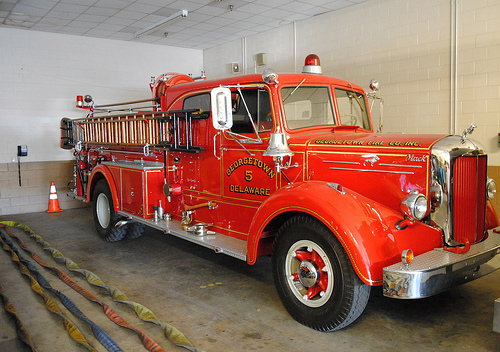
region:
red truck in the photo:
[51, 35, 485, 292]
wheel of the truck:
[283, 193, 395, 305]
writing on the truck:
[208, 141, 284, 212]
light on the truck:
[390, 183, 434, 245]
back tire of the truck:
[83, 173, 131, 248]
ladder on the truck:
[63, 100, 213, 175]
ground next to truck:
[144, 260, 206, 318]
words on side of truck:
[209, 149, 283, 210]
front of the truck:
[410, 122, 494, 276]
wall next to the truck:
[391, 28, 441, 84]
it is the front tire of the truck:
[268, 221, 355, 328]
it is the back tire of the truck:
[92, 177, 124, 242]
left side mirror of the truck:
[208, 87, 243, 132]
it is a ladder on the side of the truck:
[63, 110, 198, 151]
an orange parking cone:
[43, 176, 68, 216]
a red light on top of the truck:
[299, 53, 328, 72]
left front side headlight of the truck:
[405, 190, 430, 220]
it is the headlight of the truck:
[485, 180, 499, 199]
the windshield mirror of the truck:
[273, 85, 373, 135]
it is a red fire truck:
[66, 64, 488, 326]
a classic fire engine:
[59, 50, 499, 332]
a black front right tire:
[270, 211, 373, 330]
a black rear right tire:
[89, 176, 126, 242]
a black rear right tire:
[124, 218, 143, 237]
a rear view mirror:
[211, 85, 232, 129]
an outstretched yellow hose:
[12, 217, 200, 350]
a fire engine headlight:
[402, 192, 427, 219]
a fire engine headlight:
[484, 176, 499, 200]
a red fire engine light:
[302, 51, 326, 73]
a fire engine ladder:
[69, 106, 211, 155]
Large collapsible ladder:
[66, 107, 207, 148]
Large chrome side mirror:
[210, 77, 262, 137]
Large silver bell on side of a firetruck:
[262, 125, 297, 166]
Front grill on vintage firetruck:
[435, 135, 490, 240]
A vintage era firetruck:
[65, 52, 495, 323]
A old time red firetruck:
[67, 52, 497, 327]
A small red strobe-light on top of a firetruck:
[300, 52, 320, 67]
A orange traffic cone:
[47, 180, 61, 210]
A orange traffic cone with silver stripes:
[44, 182, 64, 209]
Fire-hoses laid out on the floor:
[0, 216, 201, 348]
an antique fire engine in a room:
[60, 53, 497, 331]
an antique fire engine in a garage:
[58, 54, 497, 330]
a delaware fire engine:
[59, 52, 497, 331]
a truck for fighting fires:
[61, 54, 498, 331]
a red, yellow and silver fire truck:
[58, 55, 497, 329]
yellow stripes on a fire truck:
[302, 142, 432, 159]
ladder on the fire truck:
[59, 106, 206, 156]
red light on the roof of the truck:
[304, 52, 321, 72]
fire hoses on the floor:
[0, 217, 202, 349]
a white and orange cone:
[47, 181, 63, 214]